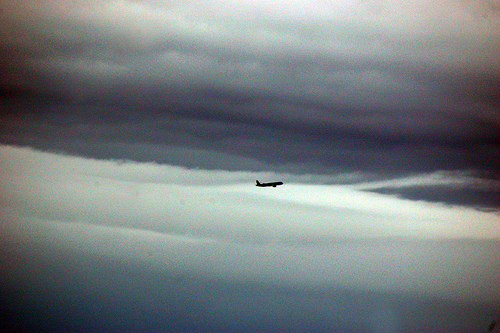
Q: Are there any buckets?
A: No, there are no buckets.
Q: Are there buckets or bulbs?
A: No, there are no buckets or bulbs.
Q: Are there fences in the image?
A: No, there are no fences.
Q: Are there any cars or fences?
A: No, there are no fences or cars.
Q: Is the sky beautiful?
A: Yes, the sky is beautiful.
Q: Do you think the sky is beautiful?
A: Yes, the sky is beautiful.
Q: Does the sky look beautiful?
A: Yes, the sky is beautiful.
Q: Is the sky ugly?
A: No, the sky is beautiful.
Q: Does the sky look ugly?
A: No, the sky is beautiful.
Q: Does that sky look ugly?
A: No, the sky is beautiful.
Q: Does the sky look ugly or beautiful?
A: The sky is beautiful.